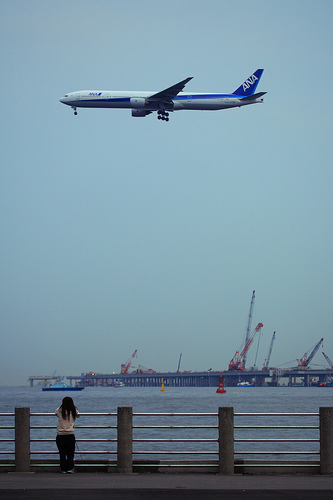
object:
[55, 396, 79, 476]
girl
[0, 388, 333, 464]
water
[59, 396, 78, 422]
hair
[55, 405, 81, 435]
shirt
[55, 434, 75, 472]
pants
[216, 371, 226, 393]
buoy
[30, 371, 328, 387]
deck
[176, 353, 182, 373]
cranes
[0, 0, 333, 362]
blue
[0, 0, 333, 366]
sky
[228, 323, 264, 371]
crane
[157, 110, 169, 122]
wheels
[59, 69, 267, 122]
plane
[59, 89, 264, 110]
white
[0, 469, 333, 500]
boardwalk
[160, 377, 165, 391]
buoy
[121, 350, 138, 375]
crane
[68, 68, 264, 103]
blue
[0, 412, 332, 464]
bars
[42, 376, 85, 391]
blue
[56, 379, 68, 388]
white